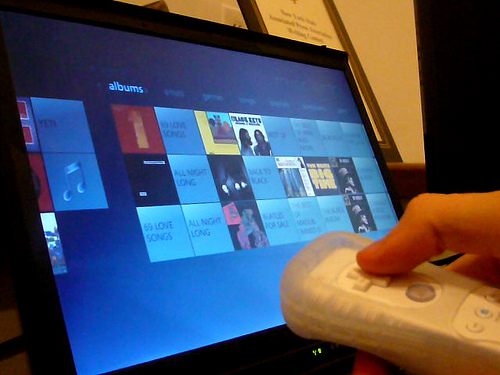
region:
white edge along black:
[401, 4, 440, 159]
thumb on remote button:
[290, 217, 432, 345]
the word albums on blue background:
[102, 71, 150, 99]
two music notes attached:
[52, 157, 97, 209]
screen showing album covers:
[18, 0, 250, 370]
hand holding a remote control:
[273, 161, 494, 367]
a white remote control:
[280, 222, 485, 365]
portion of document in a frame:
[240, 0, 358, 40]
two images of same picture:
[326, 155, 379, 235]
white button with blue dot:
[468, 301, 496, 325]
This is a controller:
[281, 205, 496, 345]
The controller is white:
[246, 266, 376, 366]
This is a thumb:
[350, 187, 496, 273]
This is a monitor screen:
[36, 25, 392, 325]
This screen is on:
[35, 56, 405, 357]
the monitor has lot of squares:
[65, 50, 371, 370]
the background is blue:
[90, 296, 220, 354]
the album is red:
[105, 93, 165, 138]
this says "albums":
[91, 65, 152, 113]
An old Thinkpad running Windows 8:
[0, 0, 409, 374]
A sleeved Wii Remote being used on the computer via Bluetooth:
[280, 230, 498, 373]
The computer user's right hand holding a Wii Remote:
[351, 191, 498, 373]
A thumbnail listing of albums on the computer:
[108, 102, 399, 263]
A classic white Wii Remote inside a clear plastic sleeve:
[313, 248, 499, 365]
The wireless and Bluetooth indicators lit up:
[309, 345, 324, 357]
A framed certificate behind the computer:
[236, 0, 404, 161]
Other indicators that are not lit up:
[326, 340, 343, 350]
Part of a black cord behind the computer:
[1, 333, 24, 361]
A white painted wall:
[332, 0, 424, 163]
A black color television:
[26, 57, 386, 370]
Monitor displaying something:
[98, 93, 276, 240]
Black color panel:
[206, 25, 316, 47]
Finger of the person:
[333, 217, 441, 276]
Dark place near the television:
[439, 21, 480, 142]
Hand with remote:
[408, 188, 489, 373]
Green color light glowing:
[309, 344, 328, 364]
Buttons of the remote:
[459, 304, 499, 348]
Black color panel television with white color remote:
[31, 143, 447, 341]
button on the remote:
[338, 244, 398, 311]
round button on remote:
[399, 279, 441, 310]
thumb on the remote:
[339, 178, 466, 294]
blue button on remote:
[466, 301, 498, 322]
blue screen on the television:
[117, 258, 219, 331]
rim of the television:
[195, 18, 277, 68]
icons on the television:
[84, 97, 306, 279]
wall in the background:
[365, 18, 412, 65]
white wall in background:
[367, 2, 408, 50]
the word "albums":
[92, 73, 152, 110]